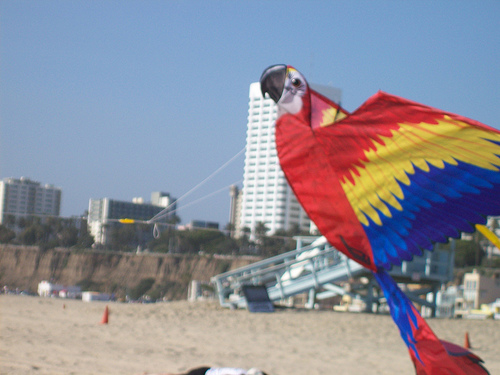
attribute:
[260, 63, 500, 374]
kite — yellow, colorful, red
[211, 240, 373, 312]
ramp — blue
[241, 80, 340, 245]
building — white, tall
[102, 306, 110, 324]
cone — orange, red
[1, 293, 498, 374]
sand — expansive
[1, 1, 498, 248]
sky — blue, cloudy, cloudless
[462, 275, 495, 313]
wall — dirty, concrete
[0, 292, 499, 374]
beach — sandy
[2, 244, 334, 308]
cliff — brown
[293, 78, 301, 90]
bird's eye — brown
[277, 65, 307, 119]
bird's face — white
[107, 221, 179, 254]
building — black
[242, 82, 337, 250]
skyscraper — white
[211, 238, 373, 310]
steps — blue